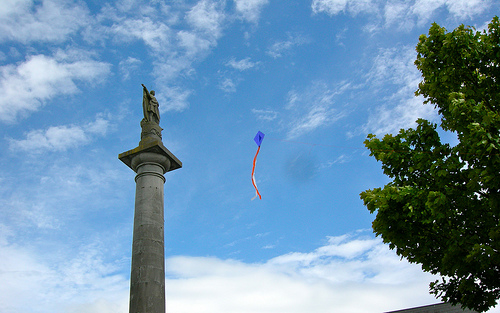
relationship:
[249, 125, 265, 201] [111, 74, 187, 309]
kite flying beside statue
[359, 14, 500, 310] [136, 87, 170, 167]
tall tree beside statue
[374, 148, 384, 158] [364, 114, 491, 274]
leaf on tree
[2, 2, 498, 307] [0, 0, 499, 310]
clouds in sky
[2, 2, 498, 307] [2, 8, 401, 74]
clouds in sky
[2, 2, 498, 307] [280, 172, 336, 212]
clouds in sky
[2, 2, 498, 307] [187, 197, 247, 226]
clouds in blue sky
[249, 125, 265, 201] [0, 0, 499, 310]
kite in sky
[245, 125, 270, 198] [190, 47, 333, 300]
kite in air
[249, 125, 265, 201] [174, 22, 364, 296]
kite in sky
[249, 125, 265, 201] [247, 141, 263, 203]
kite with tail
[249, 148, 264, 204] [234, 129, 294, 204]
string of kite